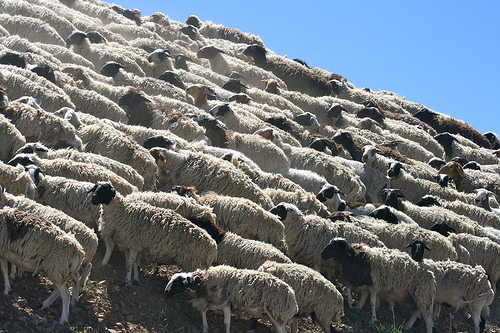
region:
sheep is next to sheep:
[94, 177, 218, 286]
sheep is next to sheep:
[159, 262, 300, 332]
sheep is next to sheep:
[257, 258, 342, 332]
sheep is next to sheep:
[322, 237, 418, 324]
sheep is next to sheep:
[2, 206, 85, 325]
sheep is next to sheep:
[418, 258, 494, 329]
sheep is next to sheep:
[228, 130, 289, 178]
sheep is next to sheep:
[78, 121, 155, 185]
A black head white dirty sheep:
[153, 270, 304, 329]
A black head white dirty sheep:
[90, 184, 197, 264]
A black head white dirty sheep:
[331, 236, 416, 328]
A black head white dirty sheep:
[271, 199, 353, 247]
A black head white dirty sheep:
[119, 89, 191, 132]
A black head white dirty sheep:
[385, 151, 415, 192]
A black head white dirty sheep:
[412, 235, 487, 316]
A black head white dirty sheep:
[63, 27, 132, 64]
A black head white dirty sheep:
[432, 124, 487, 161]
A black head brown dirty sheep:
[240, 36, 327, 91]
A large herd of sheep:
[3, 4, 498, 331]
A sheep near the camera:
[153, 259, 303, 331]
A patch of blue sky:
[130, 2, 496, 140]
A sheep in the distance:
[185, 9, 259, 46]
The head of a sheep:
[63, 26, 86, 49]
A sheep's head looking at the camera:
[358, 144, 379, 164]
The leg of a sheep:
[362, 294, 383, 323]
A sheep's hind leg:
[51, 282, 76, 323]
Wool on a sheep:
[193, 265, 293, 318]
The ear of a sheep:
[208, 83, 218, 99]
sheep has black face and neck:
[316, 240, 391, 295]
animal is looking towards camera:
[85, 171, 115, 216]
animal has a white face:
[355, 140, 370, 170]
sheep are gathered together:
[1, 65, 492, 332]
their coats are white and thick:
[107, 202, 202, 259]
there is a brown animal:
[330, 127, 407, 162]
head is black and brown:
[97, 80, 147, 125]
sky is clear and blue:
[285, 25, 486, 65]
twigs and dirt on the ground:
[84, 285, 158, 325]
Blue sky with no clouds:
[128, 0, 494, 134]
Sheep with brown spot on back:
[5, 203, 87, 332]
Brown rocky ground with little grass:
[9, 227, 499, 332]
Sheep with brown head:
[438, 159, 498, 193]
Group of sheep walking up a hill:
[4, 4, 498, 330]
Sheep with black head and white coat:
[86, 178, 217, 291]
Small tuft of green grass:
[152, 303, 180, 330]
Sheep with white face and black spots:
[314, 178, 390, 215]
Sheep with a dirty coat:
[159, 266, 299, 331]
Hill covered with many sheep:
[4, 4, 498, 323]